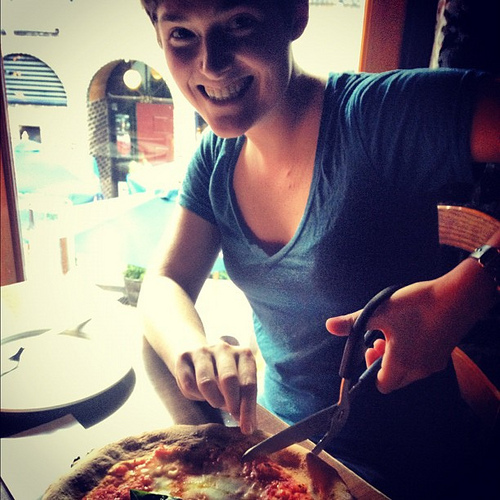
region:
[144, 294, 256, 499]
One finger holds pizza.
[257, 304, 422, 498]
Right hand scissors cut pizza.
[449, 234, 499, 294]
Silver wristwatch left arm.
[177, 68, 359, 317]
Blue v-neck short sleeve top.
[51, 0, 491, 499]
this is a woman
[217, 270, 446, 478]
a pair of shears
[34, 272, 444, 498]
woman cutting pizza with shears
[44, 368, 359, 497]
this is a pizza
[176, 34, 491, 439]
woman wearing blue shirt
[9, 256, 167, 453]
this is a dinner plate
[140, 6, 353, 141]
the woman is smiling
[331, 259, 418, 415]
black handles on shears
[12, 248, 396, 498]
pizza on a table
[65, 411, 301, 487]
brown crust on pizza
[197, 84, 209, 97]
White tooth in mouth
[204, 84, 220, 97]
White tooth in mouth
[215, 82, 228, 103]
White tooth in mouth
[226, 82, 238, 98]
White tooth in mouth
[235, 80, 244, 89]
White tooth in mouth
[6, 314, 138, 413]
White plate on table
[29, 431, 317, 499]
Small pizza in a box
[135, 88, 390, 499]
PErson wearing a blue shirt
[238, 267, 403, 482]
black handled pair of scissors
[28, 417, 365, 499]
pizza on a counter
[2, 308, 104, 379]
fork in a plate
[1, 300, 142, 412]
a round white plate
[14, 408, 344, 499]
a cheese pizza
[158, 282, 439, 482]
A woman cutting with scissors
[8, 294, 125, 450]
A white plate with fork on it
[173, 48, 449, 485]
A woman with a blue shirt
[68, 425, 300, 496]
Pizza with cheese and sauce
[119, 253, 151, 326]
A plant in a pot outside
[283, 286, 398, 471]
Blue handle scissors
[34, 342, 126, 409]
White plate on the table